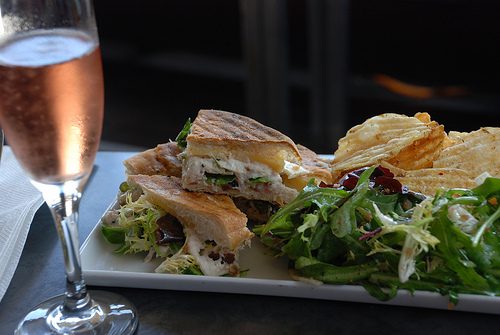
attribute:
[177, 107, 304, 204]
chicken salad — grilled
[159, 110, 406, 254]
food — nice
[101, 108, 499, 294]
food — delicious, nicely seasoned 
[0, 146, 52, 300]
napkin — white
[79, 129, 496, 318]
plate — white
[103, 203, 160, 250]
lettuce — green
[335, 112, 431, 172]
chip — potato chip, ridged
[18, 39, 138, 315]
glass — clear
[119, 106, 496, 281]
food — well prepared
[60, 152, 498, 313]
plate — oblong, white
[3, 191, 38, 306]
paper napkin — white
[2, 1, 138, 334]
glass — long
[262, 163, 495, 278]
salad — green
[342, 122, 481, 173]
chip — potato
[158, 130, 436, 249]
food — nicely prepared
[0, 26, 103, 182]
champagne — sparkling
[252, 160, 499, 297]
salad — green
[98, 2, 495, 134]
door — white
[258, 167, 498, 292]
salad — green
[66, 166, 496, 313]
plate — horizontal